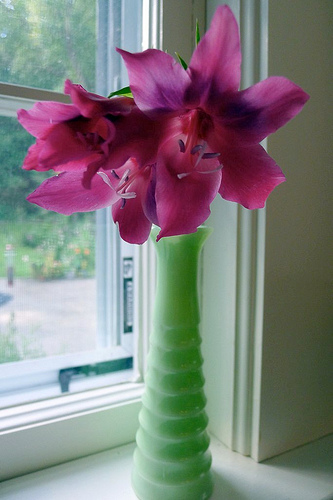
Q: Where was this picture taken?
A: On a window sill.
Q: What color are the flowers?
A: Pink.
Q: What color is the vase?
A: Green.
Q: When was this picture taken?
A: During the day.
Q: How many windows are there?
A: One.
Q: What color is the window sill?
A: White.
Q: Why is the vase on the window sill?
A: So the flowers can get sunlight.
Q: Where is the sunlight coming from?
A: Through the window.